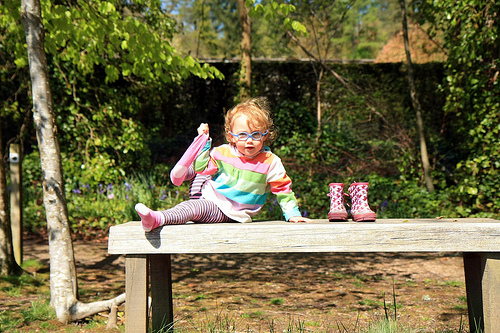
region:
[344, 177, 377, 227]
pink spotted rubber boot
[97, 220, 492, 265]
long brown wooden bench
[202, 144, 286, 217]
pink green blue child's sweater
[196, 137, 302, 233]
multi-colored striped child's sweater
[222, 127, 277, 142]
blue child's glasses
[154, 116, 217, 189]
pink sock being stretched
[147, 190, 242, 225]
pink striped girl's tights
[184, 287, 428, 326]
tall thin grass under bench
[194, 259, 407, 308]
shadows from tree canopy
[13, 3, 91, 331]
white papery tree trunk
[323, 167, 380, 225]
the boots are on the bench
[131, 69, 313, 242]
the child is on the bench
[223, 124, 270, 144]
the glasses are blue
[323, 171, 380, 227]
the boots are red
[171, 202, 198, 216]
the pants are striped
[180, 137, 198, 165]
the sock is pink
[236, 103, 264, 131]
the hair is blonde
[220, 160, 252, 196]
the shirt is striped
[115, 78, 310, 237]
the girl is pulling at the sock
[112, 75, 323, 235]
the girl is leaning on her hand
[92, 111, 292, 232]
A little girl on the bench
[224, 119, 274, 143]
A little girl wearing glasses.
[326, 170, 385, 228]
Rain boots on the table.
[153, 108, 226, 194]
The liggle girl is pulling her socks.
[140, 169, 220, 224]
The little girl is wearing striped tights.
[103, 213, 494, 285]
The bench is wooden.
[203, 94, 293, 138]
The girl has red hair.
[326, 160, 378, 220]
The boots have pink hearts on them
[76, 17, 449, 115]
Trees in the background.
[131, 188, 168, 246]
The girl is wearing pink socks.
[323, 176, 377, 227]
pink spotted rubber boots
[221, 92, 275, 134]
fine thin red hair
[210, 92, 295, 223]
young small female child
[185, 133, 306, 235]
pink green blue and white sweater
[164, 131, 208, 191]
pink sock being pulled off of right foot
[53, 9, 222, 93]
light green leafy branch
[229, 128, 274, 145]
light blue corrective lenses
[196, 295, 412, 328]
row of weeds under bench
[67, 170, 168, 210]
long purple wild flowers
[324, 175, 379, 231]
two child's white and pink boots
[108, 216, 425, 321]
wooden bench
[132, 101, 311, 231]
red-headed little girl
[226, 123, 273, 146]
child wearing blue glasses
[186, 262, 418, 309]
shadows on the ground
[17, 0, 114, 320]
tree on the left of the child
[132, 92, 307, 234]
little girl removing her sock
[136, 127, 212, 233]
pink and white socks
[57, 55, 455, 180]
building in the background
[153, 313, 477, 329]
grass growing in front of the bench